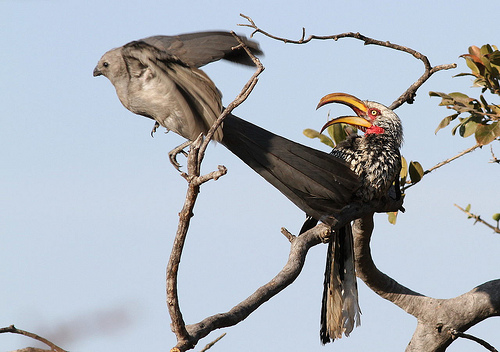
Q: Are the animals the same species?
A: Yes, all the animals are birds.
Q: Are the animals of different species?
A: No, all the animals are birds.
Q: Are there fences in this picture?
A: No, there are no fences.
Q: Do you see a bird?
A: Yes, there is a bird.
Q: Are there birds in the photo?
A: Yes, there is a bird.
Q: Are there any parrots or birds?
A: Yes, there is a bird.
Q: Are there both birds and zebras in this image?
A: No, there is a bird but no zebras.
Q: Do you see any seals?
A: No, there are no seals.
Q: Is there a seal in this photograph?
A: No, there are no seals.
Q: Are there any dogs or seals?
A: No, there are no seals or dogs.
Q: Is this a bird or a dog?
A: This is a bird.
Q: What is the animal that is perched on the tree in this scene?
A: The animal is a bird.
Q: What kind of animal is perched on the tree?
A: The animal is a bird.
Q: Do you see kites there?
A: No, there are no kites.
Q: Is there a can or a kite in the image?
A: No, there are no kites or cans.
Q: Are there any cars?
A: No, there are no cars.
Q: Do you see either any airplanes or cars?
A: No, there are no cars or airplanes.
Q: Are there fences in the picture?
A: No, there are no fences.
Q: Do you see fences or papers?
A: No, there are no fences or papers.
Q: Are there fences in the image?
A: No, there are no fences.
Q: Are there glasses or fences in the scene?
A: No, there are no fences or glasses.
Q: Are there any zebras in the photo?
A: No, there are no zebras.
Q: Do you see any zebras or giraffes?
A: No, there are no zebras or giraffes.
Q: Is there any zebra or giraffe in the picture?
A: No, there are no zebras or giraffes.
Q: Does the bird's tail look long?
A: Yes, the tail is long.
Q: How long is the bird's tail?
A: The tail is long.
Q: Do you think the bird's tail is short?
A: No, the tail is long.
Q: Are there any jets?
A: No, there are no jets.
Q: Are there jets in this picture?
A: No, there are no jets.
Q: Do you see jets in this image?
A: No, there are no jets.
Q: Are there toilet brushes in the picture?
A: No, there are no toilet brushes.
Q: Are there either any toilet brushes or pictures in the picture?
A: No, there are no toilet brushes or pictures.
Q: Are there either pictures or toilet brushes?
A: No, there are no toilet brushes or pictures.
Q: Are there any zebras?
A: No, there are no zebras.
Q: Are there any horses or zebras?
A: No, there are no zebras or horses.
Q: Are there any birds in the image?
A: Yes, there is a bird.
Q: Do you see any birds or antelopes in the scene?
A: Yes, there is a bird.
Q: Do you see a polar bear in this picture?
A: No, there are no polar bears.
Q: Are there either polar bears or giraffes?
A: No, there are no polar bears or giraffes.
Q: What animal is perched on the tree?
A: The bird is perched on the tree.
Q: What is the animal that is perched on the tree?
A: The animal is a bird.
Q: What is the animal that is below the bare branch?
A: The animal is a bird.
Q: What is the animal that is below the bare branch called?
A: The animal is a bird.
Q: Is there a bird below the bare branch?
A: Yes, there is a bird below the branch.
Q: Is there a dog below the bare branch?
A: No, there is a bird below the branch.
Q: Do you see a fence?
A: No, there are no fences.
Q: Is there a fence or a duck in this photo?
A: No, there are no fences or ducks.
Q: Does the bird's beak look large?
A: Yes, the beak is large.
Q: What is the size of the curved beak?
A: The beak is large.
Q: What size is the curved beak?
A: The beak is large.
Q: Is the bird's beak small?
A: No, the beak is large.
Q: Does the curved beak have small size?
A: No, the beak is large.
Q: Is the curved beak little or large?
A: The beak is large.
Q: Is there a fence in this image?
A: No, there are no fences.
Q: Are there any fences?
A: No, there are no fences.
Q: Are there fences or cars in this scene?
A: No, there are no fences or cars.